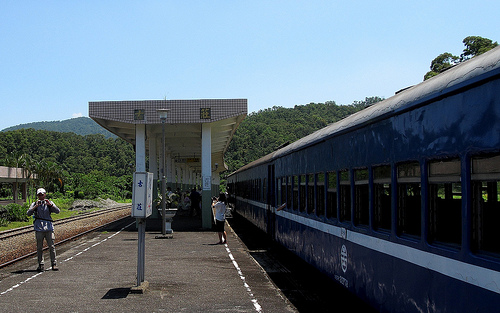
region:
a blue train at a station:
[223, 46, 497, 307]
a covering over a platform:
[80, 88, 249, 286]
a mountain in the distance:
[3, 115, 138, 141]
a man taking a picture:
[26, 183, 66, 273]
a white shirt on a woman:
[209, 200, 231, 216]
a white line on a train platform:
[216, 231, 261, 311]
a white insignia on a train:
[336, 243, 352, 270]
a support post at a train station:
[197, 118, 222, 230]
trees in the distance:
[2, 130, 135, 184]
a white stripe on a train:
[232, 196, 497, 291]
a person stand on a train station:
[24, 181, 68, 276]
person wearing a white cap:
[22, 181, 57, 212]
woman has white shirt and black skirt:
[208, 188, 235, 245]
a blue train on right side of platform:
[223, 42, 496, 310]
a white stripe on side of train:
[228, 191, 498, 288]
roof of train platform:
[76, 86, 254, 148]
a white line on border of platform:
[222, 243, 264, 310]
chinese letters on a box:
[122, 165, 159, 222]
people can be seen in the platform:
[173, 168, 204, 214]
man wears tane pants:
[16, 184, 71, 281]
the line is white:
[238, 266, 249, 293]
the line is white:
[232, 280, 258, 301]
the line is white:
[241, 272, 251, 291]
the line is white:
[244, 282, 253, 307]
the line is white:
[239, 277, 247, 306]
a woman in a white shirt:
[204, 183, 239, 252]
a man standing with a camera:
[17, 181, 82, 277]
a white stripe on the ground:
[216, 225, 268, 310]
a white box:
[110, 153, 172, 223]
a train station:
[65, 67, 292, 256]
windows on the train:
[269, 149, 481, 261]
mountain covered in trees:
[10, 97, 106, 178]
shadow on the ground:
[82, 270, 140, 309]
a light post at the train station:
[146, 100, 186, 243]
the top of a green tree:
[412, 27, 495, 65]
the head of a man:
[33, 184, 48, 201]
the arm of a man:
[23, 198, 38, 218]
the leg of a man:
[45, 231, 59, 264]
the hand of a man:
[42, 195, 52, 208]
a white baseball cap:
[34, 183, 50, 195]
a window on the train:
[366, 161, 396, 238]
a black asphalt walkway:
[0, 201, 325, 311]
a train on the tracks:
[222, 45, 499, 311]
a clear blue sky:
[0, 1, 498, 131]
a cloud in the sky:
[69, 107, 86, 119]